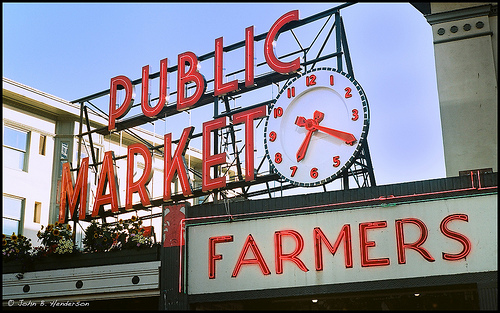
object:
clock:
[263, 66, 370, 186]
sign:
[180, 190, 499, 295]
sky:
[3, 0, 446, 199]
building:
[4, 77, 248, 253]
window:
[2, 124, 29, 172]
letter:
[273, 229, 309, 275]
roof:
[4, 77, 250, 178]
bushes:
[35, 224, 80, 254]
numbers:
[310, 74, 317, 85]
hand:
[295, 114, 357, 144]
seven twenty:
[294, 110, 358, 163]